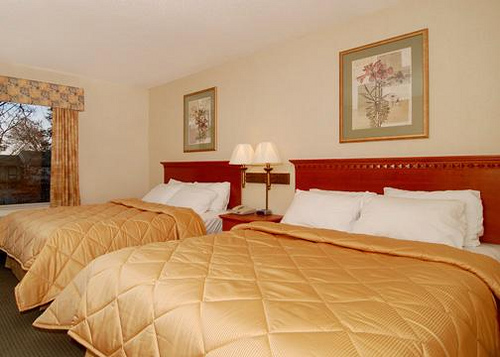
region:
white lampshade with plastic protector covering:
[250, 137, 283, 171]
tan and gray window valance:
[2, 68, 89, 114]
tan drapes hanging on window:
[45, 96, 84, 211]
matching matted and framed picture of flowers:
[174, 20, 433, 177]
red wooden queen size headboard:
[287, 148, 498, 251]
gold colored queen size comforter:
[32, 217, 497, 354]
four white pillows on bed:
[274, 182, 492, 254]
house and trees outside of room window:
[4, 94, 56, 199]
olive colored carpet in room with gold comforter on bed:
[0, 246, 91, 354]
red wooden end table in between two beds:
[217, 194, 282, 237]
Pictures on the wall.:
[103, 57, 443, 171]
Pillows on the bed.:
[263, 156, 492, 267]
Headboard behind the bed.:
[279, 135, 499, 261]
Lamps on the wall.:
[221, 125, 296, 234]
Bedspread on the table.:
[113, 167, 409, 354]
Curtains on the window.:
[6, 74, 101, 209]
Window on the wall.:
[5, 94, 82, 229]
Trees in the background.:
[3, 94, 70, 176]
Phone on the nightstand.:
[220, 193, 282, 244]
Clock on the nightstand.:
[251, 197, 271, 222]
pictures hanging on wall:
[179, 25, 429, 153]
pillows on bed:
[148, 178, 483, 251]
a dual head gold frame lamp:
[233, 145, 283, 192]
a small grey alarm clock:
[257, 207, 270, 216]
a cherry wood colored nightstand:
[221, 208, 282, 225]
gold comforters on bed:
[4, 196, 499, 355]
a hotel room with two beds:
[0, 1, 497, 351]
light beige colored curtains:
[1, 75, 83, 205]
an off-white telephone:
[229, 202, 256, 217]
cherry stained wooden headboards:
[158, 159, 499, 246]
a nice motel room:
[33, 6, 489, 352]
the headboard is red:
[292, 150, 498, 242]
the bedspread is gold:
[70, 196, 498, 355]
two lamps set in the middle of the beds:
[216, 140, 282, 200]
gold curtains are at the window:
[4, 81, 115, 229]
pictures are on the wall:
[161, 45, 453, 164]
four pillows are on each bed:
[273, 184, 486, 248]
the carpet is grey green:
[13, 319, 63, 354]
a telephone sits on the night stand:
[229, 197, 259, 217]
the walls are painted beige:
[106, 111, 141, 168]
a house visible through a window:
[0, 146, 50, 183]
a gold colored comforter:
[0, 197, 200, 307]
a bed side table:
[215, 206, 275, 226]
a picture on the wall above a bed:
[332, 20, 432, 145]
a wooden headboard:
[287, 155, 494, 240]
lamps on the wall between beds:
[225, 138, 280, 193]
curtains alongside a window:
[49, 107, 81, 205]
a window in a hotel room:
[0, 101, 52, 204]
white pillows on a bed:
[356, 183, 487, 248]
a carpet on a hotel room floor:
[1, 258, 85, 354]